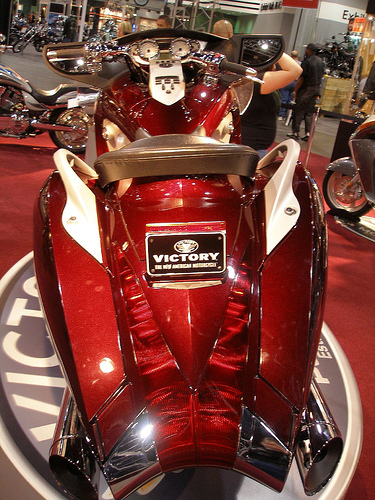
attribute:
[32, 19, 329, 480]
motorcycle — red, fancy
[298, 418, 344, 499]
exhaust pipe — chrome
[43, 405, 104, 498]
exhaust pipe — chrome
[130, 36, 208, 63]
panel — white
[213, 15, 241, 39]
man — bald, walking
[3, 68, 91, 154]
scooter — present, gray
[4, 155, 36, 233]
carpet — red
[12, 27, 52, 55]
motorcycle — black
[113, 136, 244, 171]
seat — brown, red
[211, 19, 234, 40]
head — bald